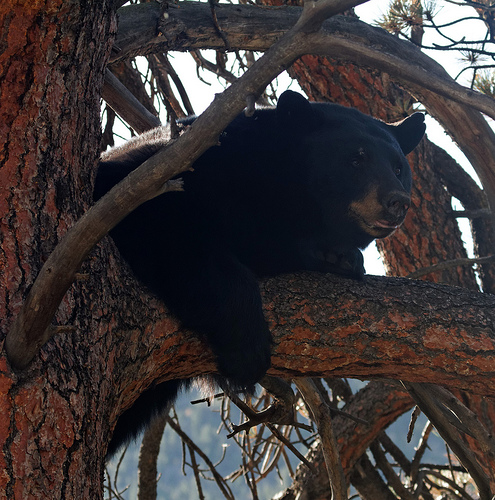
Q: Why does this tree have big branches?
A: An old tree.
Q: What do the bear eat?
A: Fish.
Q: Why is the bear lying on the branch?
A: Trying not to fall.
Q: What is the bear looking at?
A: Another animal.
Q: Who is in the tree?
A: A black bear.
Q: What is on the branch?
A: The paw of the bear.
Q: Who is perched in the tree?
A: The bear.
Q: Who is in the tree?
A: The bear.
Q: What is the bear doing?
A: Sitting in the tree.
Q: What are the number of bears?
A: One.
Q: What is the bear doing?
A: Sitting in the tree.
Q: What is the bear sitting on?
A: A tree.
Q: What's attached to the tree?
A: Several branches.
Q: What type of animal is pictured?
A: A bear.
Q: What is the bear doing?
A: Climbing a tree.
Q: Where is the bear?
A: In a tree.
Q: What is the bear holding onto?
A: A branch.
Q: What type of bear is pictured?
A: A black bear.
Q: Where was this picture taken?
A: In a tree.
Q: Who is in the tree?
A: A bear.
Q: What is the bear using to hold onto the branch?
A: Paws.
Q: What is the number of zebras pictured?
A: Zero.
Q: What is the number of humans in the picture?
A: Zero.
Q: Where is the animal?
A: In wilderness.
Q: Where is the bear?
A: On a branch.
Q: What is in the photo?
A: A bear.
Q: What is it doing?
A: Resting.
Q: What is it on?
A: A tree.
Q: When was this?
A: Daytime.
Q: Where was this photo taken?
A: In a tree.